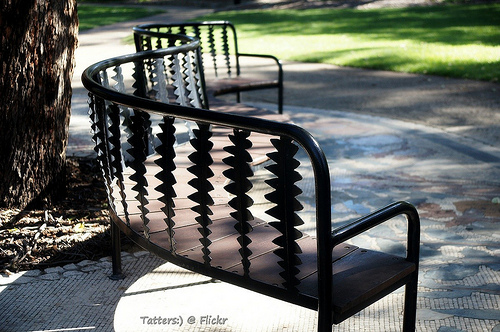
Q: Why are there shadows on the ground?
A: It's sunny.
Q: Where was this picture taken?
A: A park.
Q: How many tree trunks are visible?
A: 1.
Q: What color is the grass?
A: Green.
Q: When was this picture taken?
A: Daytime.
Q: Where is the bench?
A: In front of tree.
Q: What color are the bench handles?
A: Black.